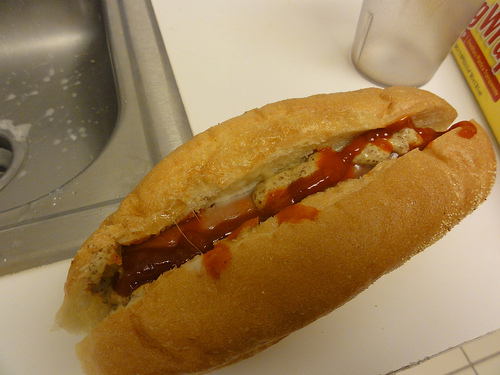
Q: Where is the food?
A: On the counter.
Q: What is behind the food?
A: A cup.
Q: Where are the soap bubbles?
A: In the sink.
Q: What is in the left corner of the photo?
A: A sink.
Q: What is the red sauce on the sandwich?
A: Ketchup.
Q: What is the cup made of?
A: Plastic.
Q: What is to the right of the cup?
A: A box of Cling Wrap.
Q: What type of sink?
A: Stainless steel.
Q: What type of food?
A: Sandwich.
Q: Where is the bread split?
A: The middle.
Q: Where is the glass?
A: Behind the sandwich.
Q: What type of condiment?
A: Ketchup.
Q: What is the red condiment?
A: Ketchup.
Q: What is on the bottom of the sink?
A: Soap suds.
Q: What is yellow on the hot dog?
A: Mustard.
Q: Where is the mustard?
A: On the hot dog.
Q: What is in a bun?
A: The hot dog.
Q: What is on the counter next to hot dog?
A: An empty cup.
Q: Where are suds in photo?
A: In the sink.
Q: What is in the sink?
A: It is empty.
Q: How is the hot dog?
A: It is uneaten.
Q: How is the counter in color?
A: White.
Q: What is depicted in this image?
A: A sandwich.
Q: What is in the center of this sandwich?
A: Red sauce.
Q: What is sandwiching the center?
A: Two bread buns.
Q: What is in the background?
A: A cup.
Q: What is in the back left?
A: A sink.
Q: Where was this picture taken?
A: A kitchen.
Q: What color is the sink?
A: Silver.